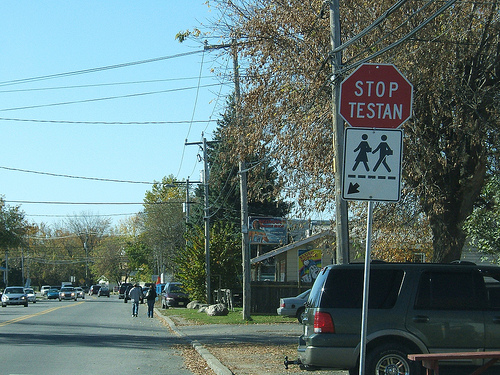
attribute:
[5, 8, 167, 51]
sky — blue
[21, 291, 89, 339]
lines — yellow, painted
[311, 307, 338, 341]
tail light — red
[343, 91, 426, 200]
sign — black, white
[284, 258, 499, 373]
car — parked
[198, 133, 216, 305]
pole — utility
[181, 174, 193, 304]
pole — utility